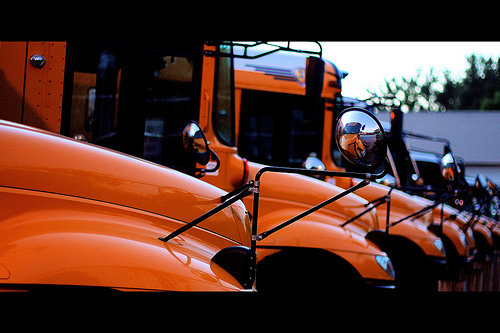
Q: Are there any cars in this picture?
A: No, there are no cars.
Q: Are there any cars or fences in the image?
A: No, there are no cars or fences.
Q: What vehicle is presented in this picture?
A: The vehicle is a school bus.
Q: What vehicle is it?
A: The vehicle is a school bus.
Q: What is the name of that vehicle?
A: This is a school bus.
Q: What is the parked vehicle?
A: The vehicle is a school bus.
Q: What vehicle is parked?
A: The vehicle is a school bus.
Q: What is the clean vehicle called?
A: The vehicle is a school bus.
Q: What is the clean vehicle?
A: The vehicle is a school bus.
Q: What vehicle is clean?
A: The vehicle is a school bus.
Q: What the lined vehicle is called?
A: The vehicle is a school bus.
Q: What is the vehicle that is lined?
A: The vehicle is a school bus.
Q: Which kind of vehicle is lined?
A: The vehicle is a school bus.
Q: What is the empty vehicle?
A: The vehicle is a school bus.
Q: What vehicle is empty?
A: The vehicle is a school bus.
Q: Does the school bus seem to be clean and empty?
A: Yes, the school bus is clean and empty.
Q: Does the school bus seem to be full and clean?
A: No, the school bus is clean but empty.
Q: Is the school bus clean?
A: Yes, the school bus is clean.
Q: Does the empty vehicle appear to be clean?
A: Yes, the school bus is clean.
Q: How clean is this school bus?
A: The school bus is clean.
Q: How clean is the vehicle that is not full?
A: The school bus is clean.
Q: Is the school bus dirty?
A: No, the school bus is clean.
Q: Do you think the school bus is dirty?
A: No, the school bus is clean.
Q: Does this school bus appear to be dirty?
A: No, the school bus is clean.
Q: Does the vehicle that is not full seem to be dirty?
A: No, the school bus is clean.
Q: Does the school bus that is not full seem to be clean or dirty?
A: The school bus is clean.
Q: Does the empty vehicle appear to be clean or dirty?
A: The school bus is clean.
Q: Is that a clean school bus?
A: Yes, that is a clean school bus.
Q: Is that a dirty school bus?
A: No, that is a clean school bus.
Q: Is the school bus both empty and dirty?
A: No, the school bus is empty but clean.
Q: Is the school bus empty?
A: Yes, the school bus is empty.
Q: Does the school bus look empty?
A: Yes, the school bus is empty.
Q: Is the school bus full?
A: No, the school bus is empty.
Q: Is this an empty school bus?
A: Yes, this is an empty school bus.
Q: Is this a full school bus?
A: No, this is an empty school bus.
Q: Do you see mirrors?
A: Yes, there is a mirror.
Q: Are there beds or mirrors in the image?
A: Yes, there is a mirror.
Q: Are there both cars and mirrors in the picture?
A: No, there is a mirror but no cars.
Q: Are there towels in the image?
A: No, there are no towels.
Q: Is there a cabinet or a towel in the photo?
A: No, there are no towels or cabinets.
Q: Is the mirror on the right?
A: Yes, the mirror is on the right of the image.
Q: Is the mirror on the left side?
A: No, the mirror is on the right of the image.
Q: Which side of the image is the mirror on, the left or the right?
A: The mirror is on the right of the image.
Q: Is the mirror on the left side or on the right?
A: The mirror is on the right of the image.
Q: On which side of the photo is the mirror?
A: The mirror is on the right of the image.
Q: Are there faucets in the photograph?
A: No, there are no faucets.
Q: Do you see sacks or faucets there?
A: No, there are no faucets or sacks.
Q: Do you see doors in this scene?
A: Yes, there is a door.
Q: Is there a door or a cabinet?
A: Yes, there is a door.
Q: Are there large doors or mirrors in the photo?
A: Yes, there is a large door.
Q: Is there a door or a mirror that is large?
A: Yes, the door is large.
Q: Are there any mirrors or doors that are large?
A: Yes, the door is large.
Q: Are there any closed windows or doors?
A: Yes, there is a closed door.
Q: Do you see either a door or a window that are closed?
A: Yes, the door is closed.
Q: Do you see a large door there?
A: Yes, there is a large door.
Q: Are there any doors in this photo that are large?
A: Yes, there is a door that is large.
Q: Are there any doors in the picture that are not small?
A: Yes, there is a large door.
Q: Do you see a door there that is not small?
A: Yes, there is a large door.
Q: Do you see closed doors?
A: Yes, there is a closed door.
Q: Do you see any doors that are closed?
A: Yes, there is a closed door.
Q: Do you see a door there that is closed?
A: Yes, there is a door that is closed.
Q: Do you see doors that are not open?
A: Yes, there is an closed door.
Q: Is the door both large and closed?
A: Yes, the door is large and closed.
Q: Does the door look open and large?
A: No, the door is large but closed.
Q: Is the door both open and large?
A: No, the door is large but closed.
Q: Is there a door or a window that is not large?
A: No, there is a door but it is large.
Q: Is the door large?
A: Yes, the door is large.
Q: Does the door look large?
A: Yes, the door is large.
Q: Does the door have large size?
A: Yes, the door is large.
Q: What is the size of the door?
A: The door is large.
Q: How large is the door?
A: The door is large.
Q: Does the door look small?
A: No, the door is large.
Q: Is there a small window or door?
A: No, there is a door but it is large.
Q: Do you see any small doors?
A: No, there is a door but it is large.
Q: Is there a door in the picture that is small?
A: No, there is a door but it is large.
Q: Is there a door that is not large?
A: No, there is a door but it is large.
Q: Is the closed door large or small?
A: The door is large.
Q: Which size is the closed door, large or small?
A: The door is large.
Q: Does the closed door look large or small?
A: The door is large.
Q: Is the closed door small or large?
A: The door is large.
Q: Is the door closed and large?
A: Yes, the door is closed and large.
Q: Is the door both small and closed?
A: No, the door is closed but large.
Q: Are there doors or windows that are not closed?
A: No, there is a door but it is closed.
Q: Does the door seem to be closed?
A: Yes, the door is closed.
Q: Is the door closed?
A: Yes, the door is closed.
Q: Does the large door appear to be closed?
A: Yes, the door is closed.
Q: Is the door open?
A: No, the door is closed.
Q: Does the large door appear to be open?
A: No, the door is closed.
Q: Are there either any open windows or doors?
A: No, there is a door but it is closed.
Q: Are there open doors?
A: No, there is a door but it is closed.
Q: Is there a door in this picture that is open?
A: No, there is a door but it is closed.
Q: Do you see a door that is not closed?
A: No, there is a door but it is closed.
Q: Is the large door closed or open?
A: The door is closed.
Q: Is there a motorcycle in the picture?
A: No, there are no motorcycles.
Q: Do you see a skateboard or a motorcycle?
A: No, there are no motorcycles or skateboards.